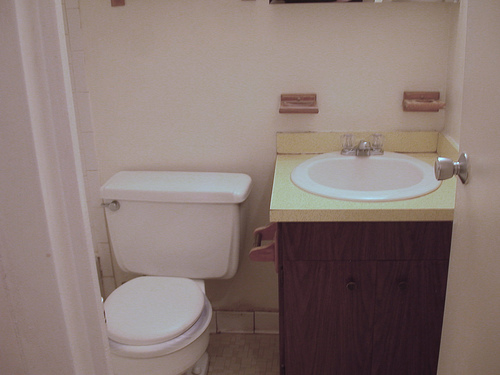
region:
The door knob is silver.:
[429, 150, 466, 185]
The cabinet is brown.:
[270, 218, 444, 373]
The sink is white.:
[297, 140, 439, 205]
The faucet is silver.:
[337, 133, 388, 160]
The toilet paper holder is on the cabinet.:
[243, 218, 274, 272]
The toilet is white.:
[90, 158, 256, 370]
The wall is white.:
[75, 1, 430, 151]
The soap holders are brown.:
[272, 80, 467, 120]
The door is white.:
[14, 8, 129, 363]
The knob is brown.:
[339, 276, 357, 294]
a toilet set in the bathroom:
[98, 170, 252, 374]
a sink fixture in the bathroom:
[268, 127, 458, 372]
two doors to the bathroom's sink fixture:
[280, 258, 450, 370]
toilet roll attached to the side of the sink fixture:
[250, 223, 278, 266]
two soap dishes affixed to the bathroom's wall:
[279, 89, 441, 114]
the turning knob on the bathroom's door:
[433, 152, 469, 187]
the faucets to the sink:
[339, 131, 387, 159]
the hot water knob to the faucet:
[340, 133, 353, 153]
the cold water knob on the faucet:
[370, 132, 382, 147]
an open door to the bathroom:
[434, 0, 499, 373]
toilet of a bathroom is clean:
[83, 148, 262, 373]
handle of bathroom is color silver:
[93, 194, 123, 219]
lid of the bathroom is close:
[103, 265, 214, 352]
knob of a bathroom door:
[423, 146, 473, 191]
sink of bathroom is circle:
[283, 141, 448, 203]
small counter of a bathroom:
[263, 122, 458, 225]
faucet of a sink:
[352, 133, 372, 156]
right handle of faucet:
[368, 122, 389, 158]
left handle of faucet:
[330, 125, 358, 156]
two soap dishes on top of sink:
[273, 84, 454, 126]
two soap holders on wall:
[277, 89, 449, 114]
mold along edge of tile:
[218, 305, 279, 319]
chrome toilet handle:
[99, 199, 122, 211]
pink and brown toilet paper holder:
[251, 219, 282, 270]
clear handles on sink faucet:
[341, 131, 388, 150]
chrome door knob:
[434, 151, 471, 185]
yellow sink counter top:
[269, 130, 463, 225]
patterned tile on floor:
[214, 340, 268, 374]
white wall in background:
[111, 31, 237, 134]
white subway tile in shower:
[66, 25, 105, 196]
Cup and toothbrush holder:
[398, 83, 454, 118]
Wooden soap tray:
[272, 84, 332, 118]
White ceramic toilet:
[84, 157, 259, 374]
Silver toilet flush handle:
[96, 195, 128, 215]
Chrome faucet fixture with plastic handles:
[333, 129, 392, 161]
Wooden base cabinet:
[282, 235, 439, 368]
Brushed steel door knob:
[425, 144, 484, 192]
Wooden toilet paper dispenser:
[248, 217, 296, 274]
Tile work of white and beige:
[220, 340, 270, 369]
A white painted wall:
[110, 37, 229, 125]